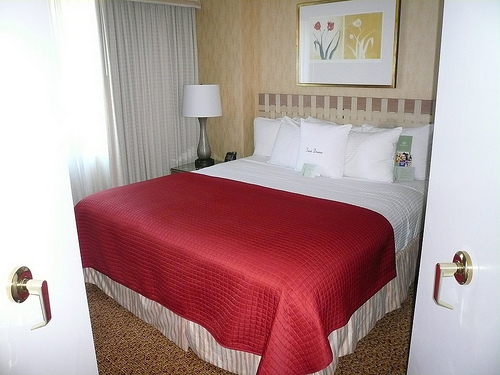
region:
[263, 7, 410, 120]
a picture hanging on a wall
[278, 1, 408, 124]
a picture hanging over a bed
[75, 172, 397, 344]
a red and white bed spread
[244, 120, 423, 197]
white pillows on a bed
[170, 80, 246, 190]
a lamp sitting on a table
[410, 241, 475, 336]
a brass door knob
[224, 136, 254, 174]
a small clock on a bed side table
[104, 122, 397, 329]
a bed that is made up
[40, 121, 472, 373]
open double doors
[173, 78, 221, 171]
a lamp with a white lamp shade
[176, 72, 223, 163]
lamp with white shade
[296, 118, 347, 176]
white pillow on bed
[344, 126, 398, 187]
white pillow on bed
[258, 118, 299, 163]
white pillow on bed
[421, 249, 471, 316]
gold handle on door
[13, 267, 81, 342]
gold handle on door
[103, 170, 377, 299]
red bedspread on bed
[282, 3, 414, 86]
framed print behind bed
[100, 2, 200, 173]
curtain hanging on window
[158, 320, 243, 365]
bedskirt around queen sized bed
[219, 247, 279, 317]
part of a sheet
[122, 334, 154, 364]
part of a carpet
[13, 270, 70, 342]
part of a handle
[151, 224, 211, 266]
edge of a bed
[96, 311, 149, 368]
part of a floor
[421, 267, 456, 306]
part of a handle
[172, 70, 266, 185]
Lamp on a table.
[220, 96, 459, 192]
Pillows on the bed.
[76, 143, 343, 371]
Red quilt on the bed.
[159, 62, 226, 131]
White lamp shade.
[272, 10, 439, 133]
Picture on the wall.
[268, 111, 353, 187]
Writing on the bed pillow.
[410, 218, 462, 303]
Knob on the door.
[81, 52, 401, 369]
Bed on the floor.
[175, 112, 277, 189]
Base of the lamp.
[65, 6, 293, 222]
Window beside the bed.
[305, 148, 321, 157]
WORDS ON THE PILLOW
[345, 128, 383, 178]
WHITE PILLOW ON THE BED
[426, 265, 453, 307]
DOOR HANDLE IS IN GOLD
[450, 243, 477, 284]
GOLD DOOR PLATE IS MOUNTED ON THE DOOR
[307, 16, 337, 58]
FLOWERS ON THE PICTURE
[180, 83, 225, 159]
WHITE LAMP ON THE SIDE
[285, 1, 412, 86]
PICTURE IS ON THE WALL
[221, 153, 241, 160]
PHONE IS ON THE DESK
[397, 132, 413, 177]
BOOK IS BEHIND THE PILLOW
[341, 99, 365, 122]
HEAD BOARD IS ON THE WALL